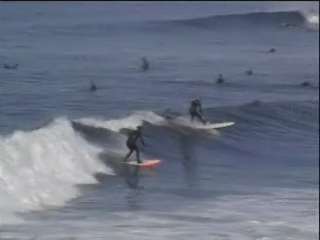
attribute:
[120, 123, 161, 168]
surfer — standing, competing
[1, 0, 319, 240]
ocean — blue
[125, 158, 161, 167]
surfboard — orange, white, red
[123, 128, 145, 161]
suit — black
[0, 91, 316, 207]
wave — rolling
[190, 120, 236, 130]
surfboard — white, large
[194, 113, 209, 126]
leg — extended